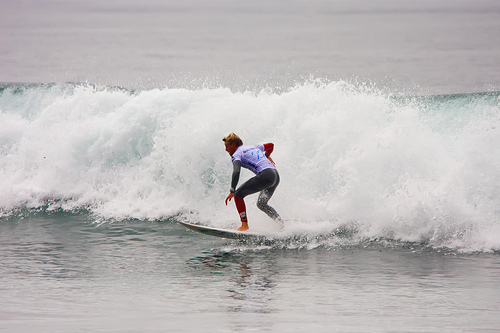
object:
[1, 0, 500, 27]
sky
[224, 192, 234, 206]
hand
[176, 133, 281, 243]
surfing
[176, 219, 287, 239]
board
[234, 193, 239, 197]
knee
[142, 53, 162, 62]
sea part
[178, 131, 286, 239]
male surfer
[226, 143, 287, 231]
wetsuit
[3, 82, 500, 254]
waves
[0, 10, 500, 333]
water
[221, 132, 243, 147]
hair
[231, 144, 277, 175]
t shirt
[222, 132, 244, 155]
head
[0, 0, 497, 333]
ocean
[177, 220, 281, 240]
surfboard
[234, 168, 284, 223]
pants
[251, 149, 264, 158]
number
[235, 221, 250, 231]
foot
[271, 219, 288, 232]
foot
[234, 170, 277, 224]
leg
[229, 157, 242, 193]
arm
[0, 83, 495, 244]
foam